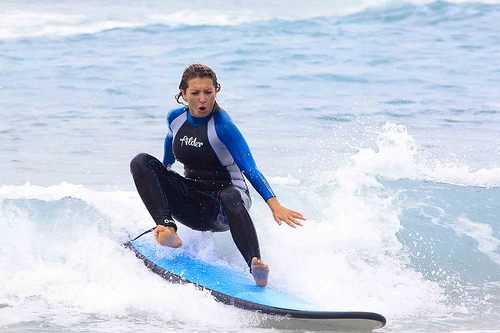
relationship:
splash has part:
[348, 114, 430, 183] [365, 120, 373, 136]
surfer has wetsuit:
[129, 64, 306, 293] [128, 104, 278, 273]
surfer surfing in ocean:
[129, 64, 306, 293] [0, 2, 500, 333]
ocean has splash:
[0, 2, 500, 333] [348, 114, 430, 183]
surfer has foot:
[129, 64, 306, 293] [248, 253, 269, 291]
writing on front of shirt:
[176, 132, 208, 152] [160, 103, 281, 204]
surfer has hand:
[129, 64, 306, 293] [270, 200, 310, 234]